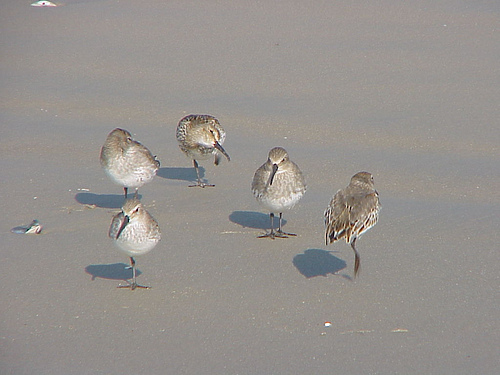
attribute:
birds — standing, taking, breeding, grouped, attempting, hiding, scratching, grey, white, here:
[79, 75, 371, 241]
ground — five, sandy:
[36, 40, 496, 359]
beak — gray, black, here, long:
[208, 143, 233, 165]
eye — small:
[134, 199, 146, 214]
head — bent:
[195, 116, 225, 147]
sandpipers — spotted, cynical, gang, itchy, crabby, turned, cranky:
[97, 76, 391, 247]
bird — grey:
[241, 152, 327, 211]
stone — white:
[300, 310, 365, 339]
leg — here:
[183, 173, 223, 193]